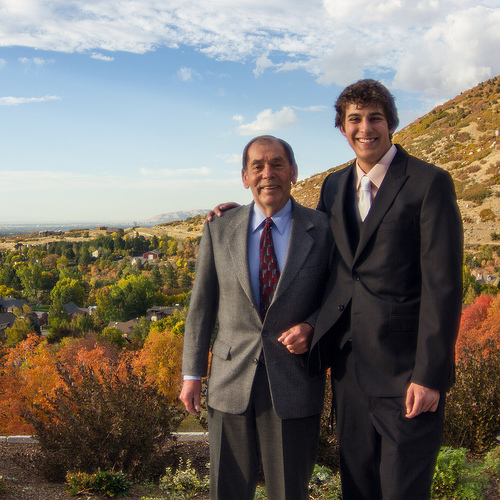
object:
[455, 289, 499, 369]
tree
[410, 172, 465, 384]
arm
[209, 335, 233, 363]
pocket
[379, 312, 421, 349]
pocket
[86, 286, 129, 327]
tree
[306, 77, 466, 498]
man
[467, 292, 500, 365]
fall tree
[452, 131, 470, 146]
tree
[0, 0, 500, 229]
sky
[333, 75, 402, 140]
curly hair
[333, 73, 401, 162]
head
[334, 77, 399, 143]
hair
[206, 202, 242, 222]
hand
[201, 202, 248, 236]
shoulder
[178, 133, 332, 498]
man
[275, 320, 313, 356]
hand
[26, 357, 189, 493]
tree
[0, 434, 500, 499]
hill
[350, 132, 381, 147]
smile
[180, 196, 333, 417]
jacket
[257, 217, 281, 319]
tie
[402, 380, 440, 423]
left hand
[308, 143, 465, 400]
black suit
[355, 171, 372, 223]
tie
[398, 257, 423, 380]
side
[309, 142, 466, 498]
suit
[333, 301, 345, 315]
button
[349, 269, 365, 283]
button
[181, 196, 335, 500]
suit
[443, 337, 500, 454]
tree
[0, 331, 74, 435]
tree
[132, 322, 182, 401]
tree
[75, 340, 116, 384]
tree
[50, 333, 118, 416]
tree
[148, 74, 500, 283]
hill